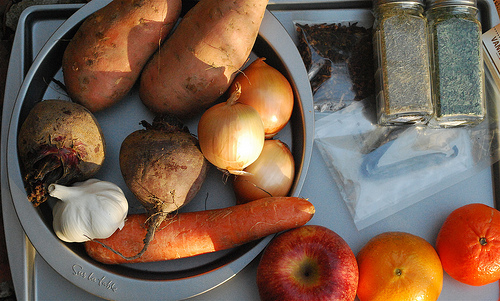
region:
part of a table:
[481, 155, 495, 174]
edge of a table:
[381, 222, 391, 249]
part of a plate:
[215, 260, 222, 270]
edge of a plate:
[206, 267, 218, 274]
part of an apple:
[308, 263, 316, 279]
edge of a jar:
[393, 80, 403, 87]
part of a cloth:
[379, 175, 383, 190]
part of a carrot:
[261, 179, 271, 211]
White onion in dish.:
[202, 102, 244, 159]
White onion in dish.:
[252, 76, 272, 126]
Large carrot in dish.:
[134, 205, 259, 240]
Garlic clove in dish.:
[55, 180, 111, 232]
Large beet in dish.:
[43, 108, 83, 175]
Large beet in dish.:
[130, 138, 196, 198]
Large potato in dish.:
[103, 32, 131, 72]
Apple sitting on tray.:
[273, 230, 323, 288]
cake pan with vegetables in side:
[36, 52, 281, 242]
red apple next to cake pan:
[252, 257, 308, 290]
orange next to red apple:
[373, 260, 399, 275]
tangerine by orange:
[455, 225, 466, 235]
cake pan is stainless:
[297, 120, 327, 151]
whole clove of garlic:
[45, 183, 118, 238]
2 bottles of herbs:
[377, 71, 482, 93]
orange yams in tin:
[63, 14, 283, 150]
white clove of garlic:
[35, 143, 121, 235]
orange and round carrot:
[82, 193, 283, 259]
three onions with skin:
[173, 74, 295, 203]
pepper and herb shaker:
[380, 11, 487, 123]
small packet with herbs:
[287, 19, 367, 109]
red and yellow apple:
[258, 220, 349, 300]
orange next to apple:
[352, 235, 445, 300]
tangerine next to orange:
[439, 209, 497, 274]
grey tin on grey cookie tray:
[45, 34, 283, 267]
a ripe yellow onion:
[203, 98, 264, 171]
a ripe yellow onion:
[233, 140, 295, 203]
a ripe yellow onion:
[240, 59, 295, 142]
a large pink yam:
[58, 1, 175, 110]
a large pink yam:
[135, 3, 270, 118]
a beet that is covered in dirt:
[112, 120, 207, 249]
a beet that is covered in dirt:
[9, 99, 105, 203]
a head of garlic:
[43, 181, 127, 244]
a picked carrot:
[85, 196, 315, 272]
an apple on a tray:
[258, 223, 359, 300]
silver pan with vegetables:
[12, 5, 316, 300]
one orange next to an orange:
[357, 193, 499, 299]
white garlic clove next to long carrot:
[45, 177, 313, 267]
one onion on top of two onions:
[194, 57, 294, 197]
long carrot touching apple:
[82, 192, 359, 299]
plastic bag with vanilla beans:
[315, 93, 498, 218]